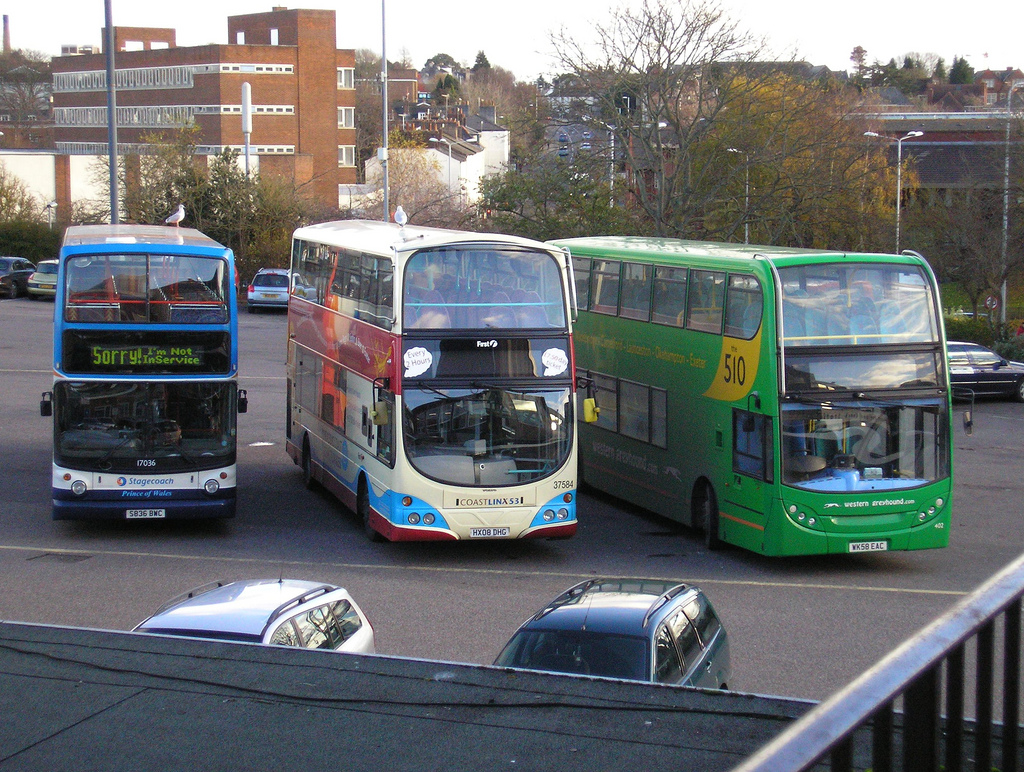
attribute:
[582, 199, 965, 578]
decker bus — green , parked 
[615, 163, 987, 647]
bus — green 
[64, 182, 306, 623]
bus — blue 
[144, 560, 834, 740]
cars — blue , white 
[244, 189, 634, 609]
bus — blue 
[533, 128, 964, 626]
bus — green 